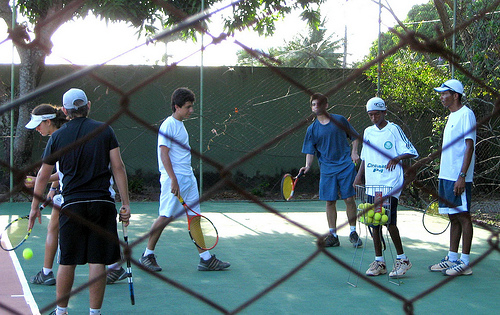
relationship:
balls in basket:
[358, 204, 395, 228] [352, 180, 398, 230]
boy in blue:
[297, 90, 363, 252] [303, 119, 359, 208]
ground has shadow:
[2, 199, 499, 315] [133, 211, 494, 307]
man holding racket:
[136, 86, 233, 286] [175, 188, 222, 254]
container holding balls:
[352, 180, 398, 230] [358, 204, 395, 228]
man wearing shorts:
[429, 77, 481, 280] [430, 177, 473, 216]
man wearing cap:
[429, 77, 481, 280] [430, 77, 466, 98]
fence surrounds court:
[4, 1, 499, 314] [0, 60, 499, 314]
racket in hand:
[175, 188, 222, 254] [169, 177, 185, 201]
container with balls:
[352, 180, 398, 230] [358, 204, 395, 228]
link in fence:
[94, 76, 156, 133] [4, 1, 499, 314]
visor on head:
[22, 111, 61, 132] [24, 98, 68, 139]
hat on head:
[62, 85, 92, 112] [61, 86, 94, 121]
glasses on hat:
[436, 83, 455, 90] [430, 77, 466, 98]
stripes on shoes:
[438, 262, 449, 272] [429, 259, 475, 278]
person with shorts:
[297, 90, 363, 252] [314, 164, 358, 203]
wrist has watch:
[456, 170, 471, 185] [456, 172, 467, 178]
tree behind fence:
[442, 0, 497, 72] [371, 0, 499, 222]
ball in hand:
[24, 173, 36, 187] [24, 171, 40, 189]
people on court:
[24, 77, 479, 315] [0, 60, 499, 314]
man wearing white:
[136, 86, 233, 286] [152, 115, 203, 219]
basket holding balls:
[352, 180, 398, 230] [358, 204, 395, 228]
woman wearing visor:
[19, 99, 70, 292] [22, 111, 61, 132]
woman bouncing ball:
[19, 99, 70, 292] [20, 245, 41, 264]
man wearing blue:
[297, 90, 363, 252] [303, 119, 359, 208]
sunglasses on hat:
[436, 83, 455, 90] [430, 77, 466, 98]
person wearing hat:
[351, 95, 420, 281] [360, 95, 388, 113]